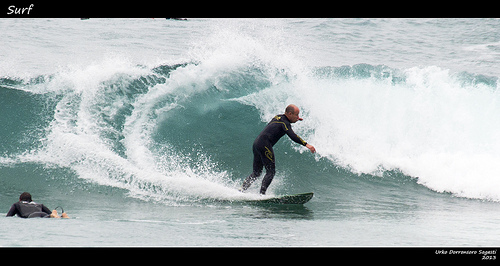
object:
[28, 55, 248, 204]
water trail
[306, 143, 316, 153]
hands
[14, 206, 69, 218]
board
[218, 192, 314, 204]
board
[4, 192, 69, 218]
man lying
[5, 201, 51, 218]
wet suit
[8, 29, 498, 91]
foam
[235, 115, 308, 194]
wetsuit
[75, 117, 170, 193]
wake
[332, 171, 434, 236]
water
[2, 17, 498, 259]
ocean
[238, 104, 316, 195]
man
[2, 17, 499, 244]
ocean water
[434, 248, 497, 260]
caption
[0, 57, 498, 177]
waves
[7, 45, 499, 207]
wave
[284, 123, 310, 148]
arm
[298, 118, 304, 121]
arm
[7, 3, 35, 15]
caption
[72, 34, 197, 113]
spray